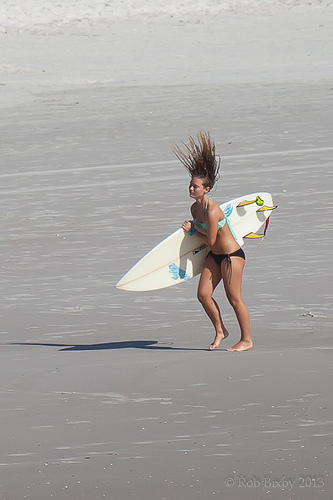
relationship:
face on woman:
[187, 178, 203, 197] [175, 122, 256, 355]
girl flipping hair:
[169, 129, 253, 353] [164, 126, 224, 196]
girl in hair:
[169, 129, 253, 353] [178, 127, 222, 173]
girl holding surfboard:
[169, 129, 253, 353] [117, 198, 276, 295]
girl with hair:
[169, 129, 253, 353] [167, 131, 219, 190]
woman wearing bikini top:
[170, 127, 254, 352] [192, 218, 224, 232]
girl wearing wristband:
[169, 129, 253, 353] [185, 221, 195, 238]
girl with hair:
[169, 129, 253, 353] [169, 124, 223, 189]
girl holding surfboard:
[169, 129, 253, 353] [113, 175, 275, 308]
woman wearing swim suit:
[170, 127, 254, 352] [188, 192, 245, 283]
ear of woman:
[203, 185, 211, 193] [175, 122, 256, 355]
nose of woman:
[185, 184, 194, 192] [170, 127, 254, 352]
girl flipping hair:
[169, 129, 253, 353] [162, 126, 228, 197]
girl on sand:
[169, 129, 253, 353] [6, 4, 328, 492]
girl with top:
[152, 114, 289, 335] [180, 202, 231, 233]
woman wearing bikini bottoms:
[170, 127, 254, 352] [206, 247, 245, 264]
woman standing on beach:
[170, 127, 254, 352] [4, 5, 329, 495]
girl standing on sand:
[169, 129, 253, 353] [4, 21, 327, 368]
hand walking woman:
[181, 219, 194, 233] [170, 127, 254, 352]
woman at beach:
[170, 127, 254, 352] [6, 99, 107, 398]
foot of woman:
[208, 328, 229, 350] [170, 127, 254, 352]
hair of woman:
[166, 128, 241, 181] [166, 128, 266, 267]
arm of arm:
[183, 210, 225, 244] [193, 210, 218, 246]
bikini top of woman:
[191, 208, 229, 232] [162, 124, 267, 351]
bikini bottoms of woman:
[206, 245, 245, 264] [170, 127, 254, 352]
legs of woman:
[193, 245, 256, 354] [180, 128, 264, 359]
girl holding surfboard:
[169, 129, 253, 353] [105, 186, 276, 303]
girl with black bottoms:
[169, 129, 253, 353] [208, 247, 247, 264]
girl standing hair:
[169, 129, 253, 353] [170, 128, 222, 192]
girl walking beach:
[169, 129, 253, 353] [8, 193, 310, 478]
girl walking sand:
[169, 129, 253, 353] [1, 215, 328, 498]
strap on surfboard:
[247, 213, 276, 245] [112, 197, 318, 264]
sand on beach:
[37, 333, 139, 404] [7, 148, 322, 487]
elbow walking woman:
[204, 239, 220, 246] [153, 129, 264, 323]